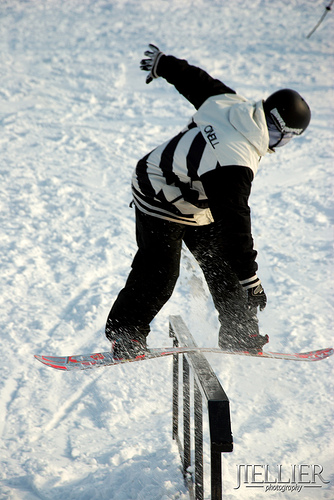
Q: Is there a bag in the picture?
A: No, there are no bags.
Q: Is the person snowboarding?
A: Yes, the person is snowboarding.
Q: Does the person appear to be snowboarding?
A: Yes, the person is snowboarding.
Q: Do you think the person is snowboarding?
A: Yes, the person is snowboarding.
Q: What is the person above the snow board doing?
A: The person is snowboarding.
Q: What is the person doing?
A: The person is snowboarding.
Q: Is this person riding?
A: No, the person is snowboarding.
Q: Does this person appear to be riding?
A: No, the person is snowboarding.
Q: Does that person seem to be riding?
A: No, the person is snowboarding.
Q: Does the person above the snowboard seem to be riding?
A: No, the person is snowboarding.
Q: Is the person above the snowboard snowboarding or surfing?
A: The person is snowboarding.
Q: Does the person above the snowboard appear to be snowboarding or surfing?
A: The person is snowboarding.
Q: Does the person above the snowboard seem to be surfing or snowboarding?
A: The person is snowboarding.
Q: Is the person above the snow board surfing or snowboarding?
A: The person is snowboarding.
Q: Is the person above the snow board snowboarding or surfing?
A: The person is snowboarding.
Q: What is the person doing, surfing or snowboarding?
A: The person is snowboarding.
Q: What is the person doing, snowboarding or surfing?
A: The person is snowboarding.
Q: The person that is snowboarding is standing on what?
A: The person is standing on the snowboard.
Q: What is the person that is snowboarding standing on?
A: The person is standing on the snowboard.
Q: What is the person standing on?
A: The person is standing on the snowboard.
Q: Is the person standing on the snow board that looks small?
A: Yes, the person is standing on the snow board.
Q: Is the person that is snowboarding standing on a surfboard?
A: No, the person is standing on the snow board.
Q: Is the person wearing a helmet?
A: Yes, the person is wearing a helmet.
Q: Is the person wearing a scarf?
A: No, the person is wearing a helmet.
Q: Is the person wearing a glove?
A: Yes, the person is wearing a glove.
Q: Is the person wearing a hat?
A: No, the person is wearing a glove.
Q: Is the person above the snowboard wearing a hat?
A: No, the person is wearing a glove.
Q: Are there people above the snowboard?
A: Yes, there is a person above the snowboard.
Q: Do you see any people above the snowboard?
A: Yes, there is a person above the snowboard.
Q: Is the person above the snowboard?
A: Yes, the person is above the snowboard.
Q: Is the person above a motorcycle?
A: No, the person is above the snowboard.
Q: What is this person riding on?
A: The person is riding on the snowboard.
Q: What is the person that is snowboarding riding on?
A: The person is riding on the snowboard.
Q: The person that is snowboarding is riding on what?
A: The person is riding on the snowboard.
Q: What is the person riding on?
A: The person is riding on the snowboard.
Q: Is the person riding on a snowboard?
A: Yes, the person is riding on a snowboard.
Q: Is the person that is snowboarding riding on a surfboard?
A: No, the person is riding on a snowboard.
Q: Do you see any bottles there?
A: No, there are no bottles.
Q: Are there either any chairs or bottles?
A: No, there are no bottles or chairs.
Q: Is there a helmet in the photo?
A: Yes, there is a helmet.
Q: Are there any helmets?
A: Yes, there is a helmet.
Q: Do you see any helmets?
A: Yes, there is a helmet.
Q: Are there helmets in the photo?
A: Yes, there is a helmet.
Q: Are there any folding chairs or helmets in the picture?
A: Yes, there is a helmet.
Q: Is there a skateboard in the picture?
A: No, there are no skateboards.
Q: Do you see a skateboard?
A: No, there are no skateboards.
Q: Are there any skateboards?
A: No, there are no skateboards.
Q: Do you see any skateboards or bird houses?
A: No, there are no skateboards or bird houses.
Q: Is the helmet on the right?
A: Yes, the helmet is on the right of the image.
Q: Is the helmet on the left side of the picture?
A: No, the helmet is on the right of the image.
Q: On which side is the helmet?
A: The helmet is on the right of the image.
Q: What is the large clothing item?
A: The clothing item is a jacket.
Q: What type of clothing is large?
A: The clothing is a jacket.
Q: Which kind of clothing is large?
A: The clothing is a jacket.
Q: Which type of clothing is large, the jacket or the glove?
A: The jacket is large.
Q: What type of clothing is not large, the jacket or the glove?
A: The glove is not large.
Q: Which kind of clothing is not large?
A: The clothing is a glove.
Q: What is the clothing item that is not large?
A: The clothing item is a glove.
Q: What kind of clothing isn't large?
A: The clothing is a glove.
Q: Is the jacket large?
A: Yes, the jacket is large.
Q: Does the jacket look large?
A: Yes, the jacket is large.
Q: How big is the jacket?
A: The jacket is large.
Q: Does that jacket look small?
A: No, the jacket is large.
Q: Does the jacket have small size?
A: No, the jacket is large.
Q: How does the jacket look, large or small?
A: The jacket is large.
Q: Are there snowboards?
A: Yes, there is a snowboard.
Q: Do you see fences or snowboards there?
A: Yes, there is a snowboard.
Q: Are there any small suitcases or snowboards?
A: Yes, there is a small snowboard.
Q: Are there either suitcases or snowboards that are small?
A: Yes, the snowboard is small.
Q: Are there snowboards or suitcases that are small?
A: Yes, the snowboard is small.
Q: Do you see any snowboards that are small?
A: Yes, there is a small snowboard.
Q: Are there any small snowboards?
A: Yes, there is a small snowboard.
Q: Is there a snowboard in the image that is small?
A: Yes, there is a snowboard that is small.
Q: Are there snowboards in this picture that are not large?
A: Yes, there is a small snowboard.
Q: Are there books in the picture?
A: No, there are no books.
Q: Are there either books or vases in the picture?
A: No, there are no books or vases.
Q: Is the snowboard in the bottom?
A: Yes, the snowboard is in the bottom of the image.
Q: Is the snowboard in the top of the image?
A: No, the snowboard is in the bottom of the image.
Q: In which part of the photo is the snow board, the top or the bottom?
A: The snow board is in the bottom of the image.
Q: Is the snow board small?
A: Yes, the snow board is small.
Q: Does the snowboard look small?
A: Yes, the snowboard is small.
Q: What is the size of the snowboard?
A: The snowboard is small.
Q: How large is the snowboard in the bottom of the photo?
A: The snowboard is small.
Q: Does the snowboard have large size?
A: No, the snowboard is small.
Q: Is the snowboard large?
A: No, the snowboard is small.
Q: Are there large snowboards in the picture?
A: No, there is a snowboard but it is small.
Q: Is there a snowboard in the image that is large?
A: No, there is a snowboard but it is small.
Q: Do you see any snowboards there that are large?
A: No, there is a snowboard but it is small.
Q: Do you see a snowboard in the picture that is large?
A: No, there is a snowboard but it is small.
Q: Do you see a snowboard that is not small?
A: No, there is a snowboard but it is small.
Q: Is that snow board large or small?
A: The snow board is small.